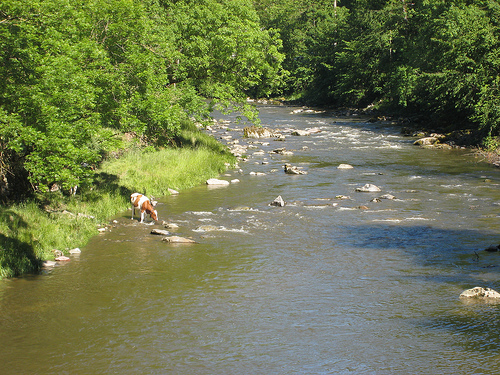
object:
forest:
[0, 0, 500, 191]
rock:
[187, 96, 452, 210]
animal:
[120, 187, 168, 229]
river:
[0, 99, 500, 375]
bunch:
[305, 0, 499, 123]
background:
[0, 0, 500, 157]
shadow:
[343, 220, 500, 348]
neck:
[147, 204, 154, 214]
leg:
[141, 210, 145, 221]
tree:
[0, 0, 500, 203]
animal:
[130, 193, 158, 224]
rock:
[458, 287, 500, 300]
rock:
[149, 211, 215, 244]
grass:
[0, 130, 232, 276]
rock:
[42, 248, 81, 267]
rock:
[169, 188, 180, 194]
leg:
[132, 206, 135, 217]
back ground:
[0, 131, 226, 278]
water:
[0, 105, 500, 375]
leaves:
[13, 5, 258, 176]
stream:
[0, 99, 497, 375]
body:
[131, 193, 149, 211]